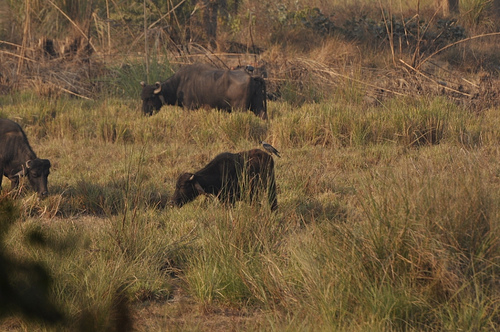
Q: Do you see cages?
A: No, there are no cages.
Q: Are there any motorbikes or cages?
A: No, there are no cages or motorbikes.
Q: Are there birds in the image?
A: Yes, there is a bird.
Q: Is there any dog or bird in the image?
A: Yes, there is a bird.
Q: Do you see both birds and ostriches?
A: No, there is a bird but no ostriches.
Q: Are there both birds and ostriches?
A: No, there is a bird but no ostriches.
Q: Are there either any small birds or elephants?
A: Yes, there is a small bird.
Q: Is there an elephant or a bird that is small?
A: Yes, the bird is small.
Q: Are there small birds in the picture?
A: Yes, there is a small bird.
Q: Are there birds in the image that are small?
A: Yes, there is a small bird.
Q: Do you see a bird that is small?
A: Yes, there is a small bird.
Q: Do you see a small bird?
A: Yes, there is a small bird.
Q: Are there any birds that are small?
A: Yes, there is a bird that is small.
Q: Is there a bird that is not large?
A: Yes, there is a small bird.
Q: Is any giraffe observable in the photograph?
A: No, there are no giraffes.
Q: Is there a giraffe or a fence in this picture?
A: No, there are no giraffes or fences.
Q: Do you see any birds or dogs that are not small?
A: No, there is a bird but it is small.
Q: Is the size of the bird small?
A: Yes, the bird is small.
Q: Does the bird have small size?
A: Yes, the bird is small.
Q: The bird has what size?
A: The bird is small.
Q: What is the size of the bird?
A: The bird is small.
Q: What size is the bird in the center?
A: The bird is small.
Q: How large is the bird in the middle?
A: The bird is small.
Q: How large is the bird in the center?
A: The bird is small.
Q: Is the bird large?
A: No, the bird is small.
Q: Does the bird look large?
A: No, the bird is small.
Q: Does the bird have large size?
A: No, the bird is small.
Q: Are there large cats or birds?
A: No, there is a bird but it is small.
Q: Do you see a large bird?
A: No, there is a bird but it is small.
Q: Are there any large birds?
A: No, there is a bird but it is small.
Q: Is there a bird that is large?
A: No, there is a bird but it is small.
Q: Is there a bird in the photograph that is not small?
A: No, there is a bird but it is small.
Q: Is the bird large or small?
A: The bird is small.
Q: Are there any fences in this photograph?
A: No, there are no fences.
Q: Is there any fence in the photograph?
A: No, there are no fences.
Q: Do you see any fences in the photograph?
A: No, there are no fences.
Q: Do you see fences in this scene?
A: No, there are no fences.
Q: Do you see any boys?
A: No, there are no boys.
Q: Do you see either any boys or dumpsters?
A: No, there are no boys or dumpsters.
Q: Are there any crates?
A: No, there are no crates.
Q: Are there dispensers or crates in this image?
A: No, there are no crates or dispensers.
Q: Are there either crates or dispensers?
A: No, there are no crates or dispensers.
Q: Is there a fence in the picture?
A: No, there are no fences.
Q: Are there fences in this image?
A: No, there are no fences.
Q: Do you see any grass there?
A: Yes, there is grass.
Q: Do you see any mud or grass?
A: Yes, there is grass.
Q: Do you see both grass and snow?
A: No, there is grass but no snow.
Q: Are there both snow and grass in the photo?
A: No, there is grass but no snow.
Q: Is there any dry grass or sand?
A: Yes, there is dry grass.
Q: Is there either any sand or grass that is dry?
A: Yes, the grass is dry.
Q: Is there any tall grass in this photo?
A: Yes, there is tall grass.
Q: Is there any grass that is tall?
A: Yes, there is grass that is tall.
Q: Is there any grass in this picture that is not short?
A: Yes, there is tall grass.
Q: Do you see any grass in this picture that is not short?
A: Yes, there is tall grass.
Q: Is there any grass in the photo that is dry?
A: Yes, there is dry grass.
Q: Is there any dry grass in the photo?
A: Yes, there is dry grass.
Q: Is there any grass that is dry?
A: Yes, there is grass that is dry.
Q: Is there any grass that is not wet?
A: Yes, there is dry grass.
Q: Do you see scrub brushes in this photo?
A: No, there are no scrub brushes.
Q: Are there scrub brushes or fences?
A: No, there are no scrub brushes or fences.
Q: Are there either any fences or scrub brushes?
A: No, there are no scrub brushes or fences.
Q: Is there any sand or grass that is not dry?
A: No, there is grass but it is dry.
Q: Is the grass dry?
A: Yes, the grass is dry.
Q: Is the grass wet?
A: No, the grass is dry.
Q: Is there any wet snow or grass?
A: No, there is grass but it is dry.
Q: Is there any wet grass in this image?
A: No, there is grass but it is dry.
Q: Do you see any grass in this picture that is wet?
A: No, there is grass but it is dry.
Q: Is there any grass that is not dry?
A: No, there is grass but it is dry.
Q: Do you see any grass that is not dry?
A: No, there is grass but it is dry.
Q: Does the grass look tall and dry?
A: Yes, the grass is tall and dry.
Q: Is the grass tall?
A: Yes, the grass is tall.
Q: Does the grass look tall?
A: Yes, the grass is tall.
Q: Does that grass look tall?
A: Yes, the grass is tall.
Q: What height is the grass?
A: The grass is tall.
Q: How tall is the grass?
A: The grass is tall.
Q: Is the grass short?
A: No, the grass is tall.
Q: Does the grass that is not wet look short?
A: No, the grass is tall.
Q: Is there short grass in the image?
A: No, there is grass but it is tall.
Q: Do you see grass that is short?
A: No, there is grass but it is tall.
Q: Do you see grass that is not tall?
A: No, there is grass but it is tall.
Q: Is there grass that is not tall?
A: No, there is grass but it is tall.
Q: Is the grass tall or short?
A: The grass is tall.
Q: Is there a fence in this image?
A: No, there are no fences.